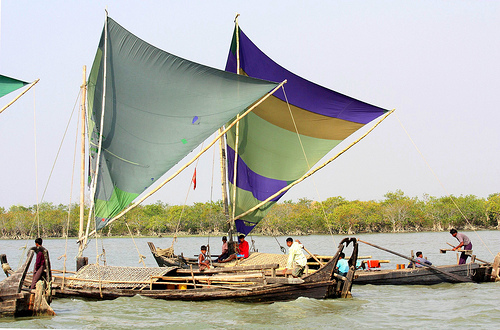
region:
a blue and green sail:
[220, 23, 393, 239]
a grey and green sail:
[87, 15, 285, 243]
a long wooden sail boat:
[1, 233, 360, 303]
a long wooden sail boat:
[144, 240, 499, 287]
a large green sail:
[0, 68, 27, 100]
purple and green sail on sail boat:
[221, 13, 402, 259]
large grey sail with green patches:
[84, 11, 281, 229]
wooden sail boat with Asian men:
[150, 228, 355, 304]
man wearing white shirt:
[283, 240, 305, 272]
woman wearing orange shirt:
[236, 241, 249, 257]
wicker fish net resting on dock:
[68, 255, 178, 295]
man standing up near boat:
[28, 230, 51, 285]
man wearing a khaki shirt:
[455, 234, 471, 249]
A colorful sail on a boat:
[222, 26, 390, 236]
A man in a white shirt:
[283, 234, 304, 279]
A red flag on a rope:
[187, 166, 201, 188]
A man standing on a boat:
[27, 234, 52, 279]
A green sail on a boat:
[78, 17, 276, 224]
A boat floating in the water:
[360, 263, 486, 284]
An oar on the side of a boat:
[360, 236, 462, 283]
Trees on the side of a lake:
[332, 188, 498, 228]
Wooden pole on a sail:
[76, 65, 88, 274]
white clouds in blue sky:
[382, 145, 402, 160]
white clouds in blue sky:
[405, 140, 437, 174]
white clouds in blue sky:
[422, 43, 450, 79]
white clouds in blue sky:
[360, 37, 396, 73]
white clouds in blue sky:
[447, 25, 477, 67]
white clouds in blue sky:
[319, 23, 356, 55]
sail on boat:
[215, 32, 382, 197]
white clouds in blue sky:
[394, 59, 442, 110]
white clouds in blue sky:
[352, 163, 376, 181]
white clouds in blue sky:
[397, 35, 431, 69]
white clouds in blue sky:
[17, 122, 48, 142]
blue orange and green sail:
[213, 13, 398, 241]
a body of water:
[1, 229, 496, 329]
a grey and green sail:
[75, 8, 297, 252]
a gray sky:
[6, 5, 498, 235]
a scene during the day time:
[10, 5, 497, 311]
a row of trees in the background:
[0, 190, 497, 256]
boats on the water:
[2, 209, 499, 321]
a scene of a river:
[1, 225, 496, 328]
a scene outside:
[2, 5, 497, 329]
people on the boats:
[3, 215, 495, 307]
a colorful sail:
[213, 10, 397, 272]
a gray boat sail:
[84, 20, 299, 250]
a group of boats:
[17, 222, 497, 324]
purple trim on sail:
[224, 26, 388, 126]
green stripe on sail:
[224, 103, 333, 195]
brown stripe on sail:
[232, 67, 357, 152]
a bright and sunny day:
[13, 15, 494, 319]